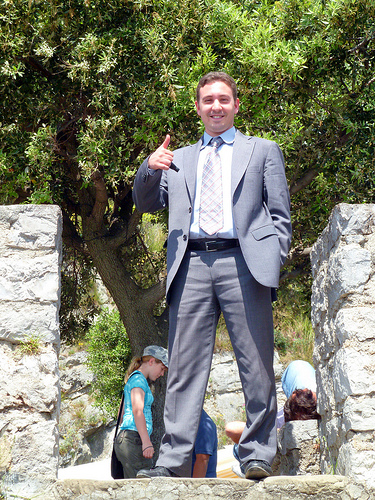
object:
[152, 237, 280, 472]
pants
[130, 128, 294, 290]
shirt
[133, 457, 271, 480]
shoes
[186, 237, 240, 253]
belt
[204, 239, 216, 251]
buckle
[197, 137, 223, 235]
tie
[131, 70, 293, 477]
man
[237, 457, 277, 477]
shoe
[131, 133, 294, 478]
grey suit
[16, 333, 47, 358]
plant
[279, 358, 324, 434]
lady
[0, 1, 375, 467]
tree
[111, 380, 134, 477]
bag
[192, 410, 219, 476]
blue t-shirt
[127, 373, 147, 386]
shoulder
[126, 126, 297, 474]
suit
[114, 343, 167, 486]
person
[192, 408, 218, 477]
person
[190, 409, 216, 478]
shirt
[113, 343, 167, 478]
girl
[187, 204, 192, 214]
button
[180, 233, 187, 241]
button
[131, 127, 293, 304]
jacket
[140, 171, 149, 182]
button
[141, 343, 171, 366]
cap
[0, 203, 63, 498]
wall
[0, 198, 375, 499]
rock wall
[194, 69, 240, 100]
short hair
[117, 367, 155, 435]
shirt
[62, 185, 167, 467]
tree trunk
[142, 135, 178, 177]
thumbs up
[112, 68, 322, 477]
people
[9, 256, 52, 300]
stones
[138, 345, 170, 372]
hat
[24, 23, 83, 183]
rope